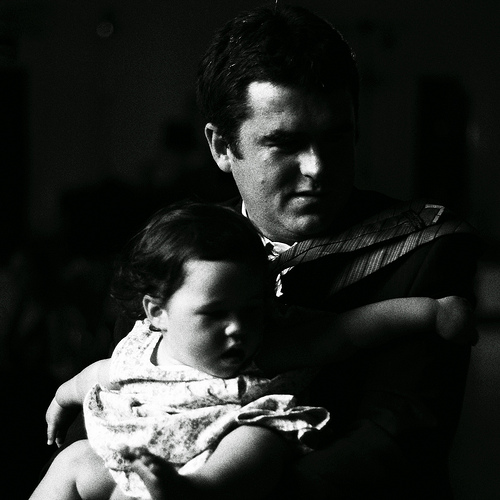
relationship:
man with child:
[108, 1, 481, 499] [24, 198, 484, 499]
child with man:
[24, 198, 484, 499] [108, 1, 481, 499]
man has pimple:
[108, 1, 481, 499] [260, 177, 270, 189]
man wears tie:
[108, 1, 481, 499] [270, 199, 478, 311]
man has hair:
[108, 1, 481, 499] [197, 3, 363, 163]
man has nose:
[108, 1, 481, 499] [294, 141, 326, 183]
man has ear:
[108, 1, 481, 499] [202, 119, 236, 174]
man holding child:
[108, 1, 481, 499] [24, 198, 484, 499]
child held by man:
[24, 198, 484, 499] [108, 1, 481, 499]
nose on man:
[294, 141, 326, 183] [108, 1, 481, 499]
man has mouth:
[108, 1, 481, 499] [290, 187, 327, 203]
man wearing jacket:
[108, 1, 481, 499] [109, 184, 484, 499]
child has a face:
[24, 198, 484, 499] [188, 286, 270, 378]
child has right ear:
[24, 198, 484, 499] [140, 292, 169, 333]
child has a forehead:
[24, 198, 484, 499] [179, 256, 270, 301]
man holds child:
[108, 1, 481, 499] [24, 198, 484, 499]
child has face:
[24, 198, 484, 499] [188, 286, 270, 378]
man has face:
[108, 1, 481, 499] [246, 110, 356, 233]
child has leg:
[24, 198, 484, 499] [118, 426, 295, 499]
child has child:
[24, 198, 484, 499] [40, 198, 484, 499]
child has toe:
[24, 198, 484, 499] [115, 442, 131, 460]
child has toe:
[24, 198, 484, 499] [133, 447, 149, 459]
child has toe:
[24, 198, 484, 499] [141, 453, 158, 464]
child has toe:
[24, 198, 484, 499] [148, 463, 166, 477]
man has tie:
[108, 1, 481, 499] [270, 199, 478, 311]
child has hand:
[24, 198, 484, 499] [435, 296, 482, 351]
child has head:
[24, 198, 484, 499] [116, 198, 274, 383]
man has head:
[108, 1, 481, 499] [196, 2, 362, 245]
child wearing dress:
[24, 198, 484, 499] [82, 317, 333, 496]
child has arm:
[24, 198, 484, 499] [44, 356, 136, 408]